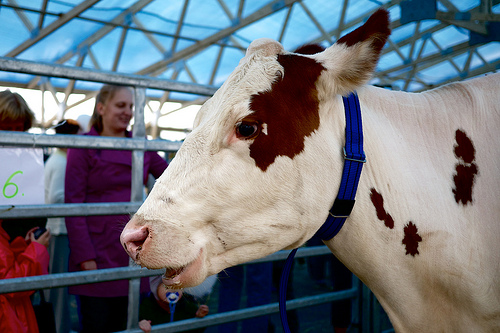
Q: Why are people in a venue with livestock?
A: Stockyard show.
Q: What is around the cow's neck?
A: Blue collar.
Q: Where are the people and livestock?
A: Venue.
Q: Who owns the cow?
A: Farmer.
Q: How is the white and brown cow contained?
A: Metal fence.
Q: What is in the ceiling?
A: Metal beams.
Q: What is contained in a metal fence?
A: White and brown spotted cow.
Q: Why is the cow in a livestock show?
A: To market.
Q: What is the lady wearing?
A: Jacket.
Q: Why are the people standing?
A: For event.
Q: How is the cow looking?
A: Straight.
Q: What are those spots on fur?
A: Brown.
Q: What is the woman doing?
A: Smiling.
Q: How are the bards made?
A: Metal.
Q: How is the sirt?
A: Purple.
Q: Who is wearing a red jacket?
A: Child bottom left.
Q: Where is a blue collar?
A: Cow's neck.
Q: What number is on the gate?
A: Six.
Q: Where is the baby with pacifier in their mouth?
A: Under cows mouth.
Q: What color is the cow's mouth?
A: Pink.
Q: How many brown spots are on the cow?
A: 5.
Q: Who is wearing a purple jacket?
A: Blonde woman.